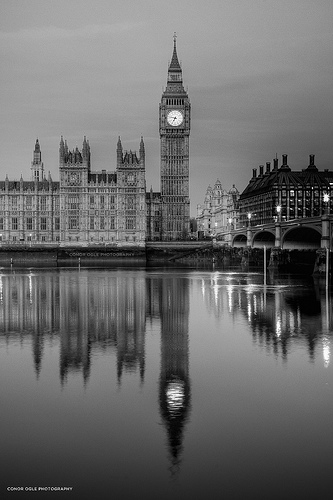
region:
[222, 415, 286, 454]
the water is pure clear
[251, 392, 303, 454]
the water is pure clear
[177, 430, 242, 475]
the water is pure clear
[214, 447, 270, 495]
the water is pure clear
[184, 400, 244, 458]
the water is pure clear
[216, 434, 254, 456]
the water is pure clear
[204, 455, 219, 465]
the water is pure clear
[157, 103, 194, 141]
a large round clock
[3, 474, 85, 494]
the photography name and label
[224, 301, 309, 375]
small ripples in the water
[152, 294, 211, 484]
the reflection of a clocktower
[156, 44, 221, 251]
a tall clock tower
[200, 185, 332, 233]
a few street lights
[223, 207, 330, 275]
a bridge over the water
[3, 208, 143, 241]
a row of windows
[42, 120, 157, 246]
a few towers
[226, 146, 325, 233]
a building with multiple chimney stacks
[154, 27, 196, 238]
clock tower in london, england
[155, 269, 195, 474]
reflection of clock tower in water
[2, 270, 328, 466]
reflection of buildings on the water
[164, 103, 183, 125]
large round clock on tower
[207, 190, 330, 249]
bridge over body of water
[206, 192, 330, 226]
lit lights on bridge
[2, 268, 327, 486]
section of a large body of water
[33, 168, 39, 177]
windows on building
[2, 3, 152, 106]
patch of sky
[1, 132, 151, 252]
parliment building in london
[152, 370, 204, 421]
reflection of a clock in the water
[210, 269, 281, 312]
reflection of lights in the water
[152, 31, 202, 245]
ornate clock tower taller than the other buildings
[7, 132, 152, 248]
ornate many windowed building by the water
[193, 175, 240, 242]
building with many domes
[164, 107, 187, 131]
clock face on a tower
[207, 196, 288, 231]
lights on a bridge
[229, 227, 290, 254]
bridge with arches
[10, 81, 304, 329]
buildings on the water's edge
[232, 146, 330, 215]
large building with many chimneys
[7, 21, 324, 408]
historic buildings along a river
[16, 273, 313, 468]
calm and dark water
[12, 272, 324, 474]
reflection of lights and buildings on river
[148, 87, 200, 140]
lighted clock on tower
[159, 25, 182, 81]
spire higher than any surrounding buildings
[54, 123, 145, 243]
symmetrical towers between shorter building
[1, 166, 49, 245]
repeated cylindrical design between windows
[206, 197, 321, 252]
arches on the bottom of the bridge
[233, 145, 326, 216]
dark building with chimneys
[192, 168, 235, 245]
light-colored building with towers of different heights